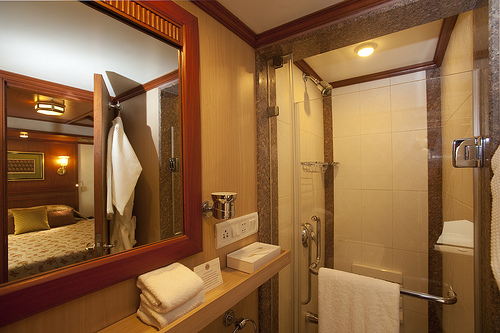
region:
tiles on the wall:
[336, 113, 407, 224]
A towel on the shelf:
[148, 273, 195, 318]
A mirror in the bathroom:
[49, 98, 134, 235]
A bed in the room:
[30, 220, 70, 266]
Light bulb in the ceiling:
[353, 27, 379, 67]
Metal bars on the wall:
[298, 210, 334, 277]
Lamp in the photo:
[207, 185, 236, 227]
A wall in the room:
[443, 90, 475, 137]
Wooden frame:
[180, 135, 215, 233]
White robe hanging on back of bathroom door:
[106, 97, 137, 252]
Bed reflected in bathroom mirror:
[0, 183, 109, 286]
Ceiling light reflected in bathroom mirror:
[28, 96, 70, 119]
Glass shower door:
[275, 63, 474, 331]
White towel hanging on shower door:
[314, 260, 406, 330]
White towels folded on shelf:
[130, 258, 207, 329]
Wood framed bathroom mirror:
[0, 0, 204, 320]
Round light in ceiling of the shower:
[352, 43, 378, 58]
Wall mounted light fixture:
[55, 152, 71, 177]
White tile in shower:
[349, 106, 409, 216]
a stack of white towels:
[134, 262, 210, 329]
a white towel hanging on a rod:
[308, 264, 400, 329]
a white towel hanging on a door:
[105, 103, 142, 256]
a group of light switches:
[210, 212, 264, 249]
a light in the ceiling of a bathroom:
[350, 41, 377, 60]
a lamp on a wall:
[55, 151, 69, 176]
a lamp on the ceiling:
[30, 98, 66, 118]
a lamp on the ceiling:
[16, 130, 31, 139]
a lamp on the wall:
[198, 186, 239, 223]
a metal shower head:
[298, 65, 335, 97]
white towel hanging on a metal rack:
[308, 263, 458, 332]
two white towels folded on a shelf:
[131, 260, 204, 326]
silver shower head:
[302, 74, 331, 95]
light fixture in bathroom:
[352, 41, 377, 58]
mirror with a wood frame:
[0, 1, 202, 329]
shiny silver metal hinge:
[450, 137, 492, 170]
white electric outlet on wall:
[213, 210, 260, 249]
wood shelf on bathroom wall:
[97, 239, 292, 331]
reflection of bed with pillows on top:
[8, 202, 93, 279]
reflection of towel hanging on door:
[91, 74, 139, 257]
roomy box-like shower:
[258, 0, 490, 329]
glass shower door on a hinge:
[291, 65, 489, 331]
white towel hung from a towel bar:
[306, 265, 456, 332]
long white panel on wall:
[214, 209, 259, 248]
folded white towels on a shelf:
[131, 261, 204, 331]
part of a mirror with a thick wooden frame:
[0, 0, 203, 331]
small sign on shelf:
[193, 257, 235, 312]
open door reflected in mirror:
[84, 72, 117, 253]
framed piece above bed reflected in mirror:
[4, 150, 96, 282]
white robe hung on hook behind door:
[92, 73, 144, 255]